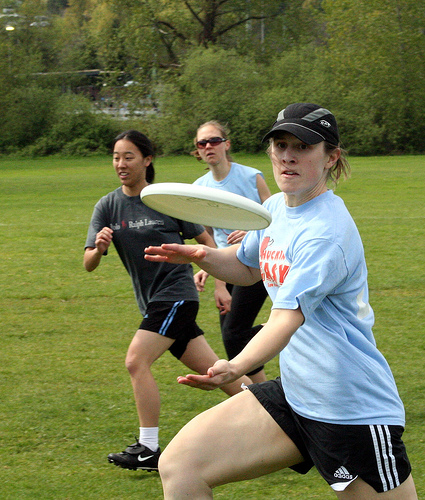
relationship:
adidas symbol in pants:
[330, 463, 357, 481] [254, 379, 409, 494]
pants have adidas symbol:
[254, 379, 409, 494] [330, 463, 357, 481]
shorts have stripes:
[136, 300, 206, 363] [157, 293, 183, 334]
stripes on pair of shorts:
[336, 408, 407, 494] [240, 361, 416, 497]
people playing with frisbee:
[74, 97, 415, 498] [138, 181, 274, 235]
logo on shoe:
[134, 451, 155, 461] [104, 439, 165, 473]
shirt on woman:
[83, 184, 205, 316] [83, 127, 254, 472]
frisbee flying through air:
[140, 182, 270, 231] [21, 40, 422, 428]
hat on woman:
[265, 84, 368, 153] [80, 99, 197, 484]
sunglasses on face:
[193, 134, 224, 149] [194, 125, 228, 166]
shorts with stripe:
[138, 300, 204, 359] [158, 301, 178, 333]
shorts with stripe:
[138, 300, 204, 359] [162, 300, 183, 334]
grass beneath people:
[0, 156, 424, 499] [153, 97, 423, 499]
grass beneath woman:
[0, 156, 424, 499] [188, 118, 272, 386]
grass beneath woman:
[0, 156, 424, 499] [83, 127, 254, 472]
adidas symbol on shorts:
[328, 461, 357, 482] [263, 372, 412, 483]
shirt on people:
[222, 193, 414, 406] [153, 97, 423, 499]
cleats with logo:
[106, 439, 164, 483] [135, 449, 155, 464]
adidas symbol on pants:
[330, 463, 357, 481] [238, 372, 414, 497]